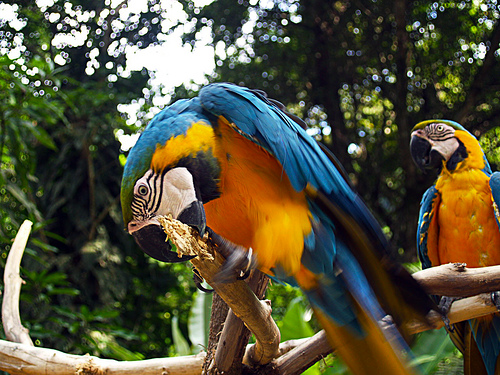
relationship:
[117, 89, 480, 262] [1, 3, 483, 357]
parrots standing on tree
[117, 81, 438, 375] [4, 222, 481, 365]
parrots standing on branch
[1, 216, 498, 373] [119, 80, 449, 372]
tree with parrots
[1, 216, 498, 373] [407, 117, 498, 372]
tree with parrots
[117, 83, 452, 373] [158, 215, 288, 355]
bird eating branch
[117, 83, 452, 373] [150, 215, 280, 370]
bird holding branch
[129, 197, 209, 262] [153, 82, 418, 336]
beak of parrot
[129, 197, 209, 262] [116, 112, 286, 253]
beak of parrot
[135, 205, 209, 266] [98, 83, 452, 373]
beak of parrot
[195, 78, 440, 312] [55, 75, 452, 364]
wing of parrot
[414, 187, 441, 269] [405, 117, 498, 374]
wing of parrot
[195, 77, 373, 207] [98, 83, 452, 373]
wing of parrot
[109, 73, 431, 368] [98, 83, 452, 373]
claw of parrot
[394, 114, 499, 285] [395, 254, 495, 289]
bird on branch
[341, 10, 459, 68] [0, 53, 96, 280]
leaves on tree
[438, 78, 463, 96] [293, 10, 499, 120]
leaves on tree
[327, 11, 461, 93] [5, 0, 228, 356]
leaves on tree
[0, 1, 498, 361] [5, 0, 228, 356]
leaves on tree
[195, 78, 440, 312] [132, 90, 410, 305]
wing of parrot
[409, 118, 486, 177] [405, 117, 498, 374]
head of parrot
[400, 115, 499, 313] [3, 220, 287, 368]
parrot hanging on branch